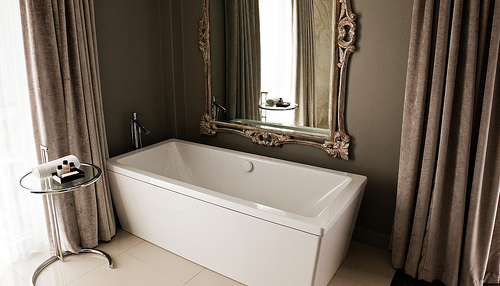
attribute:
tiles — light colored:
[6, 231, 398, 285]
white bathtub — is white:
[105, 135, 370, 285]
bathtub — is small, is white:
[74, 80, 407, 278]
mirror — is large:
[206, 0, 338, 143]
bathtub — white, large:
[104, 133, 369, 284]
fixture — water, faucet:
[127, 110, 149, 153]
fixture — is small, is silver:
[110, 97, 167, 158]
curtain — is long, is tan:
[395, 4, 497, 284]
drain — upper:
[237, 151, 284, 185]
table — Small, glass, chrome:
[2, 143, 117, 280]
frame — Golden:
[195, 30, 399, 147]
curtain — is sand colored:
[15, 0, 118, 260]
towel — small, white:
[33, 151, 80, 175]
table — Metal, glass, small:
[19, 141, 115, 283]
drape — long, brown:
[390, 0, 498, 283]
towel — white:
[30, 144, 88, 181]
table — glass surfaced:
[0, 132, 129, 252]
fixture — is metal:
[123, 112, 146, 149]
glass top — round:
[18, 159, 108, 206]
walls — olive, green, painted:
[181, 2, 420, 229]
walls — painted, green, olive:
[88, 2, 169, 163]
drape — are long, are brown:
[411, 110, 478, 215]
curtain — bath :
[387, 0, 499, 282]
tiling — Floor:
[131, 263, 181, 283]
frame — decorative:
[323, 2, 381, 176]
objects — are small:
[54, 152, 82, 179]